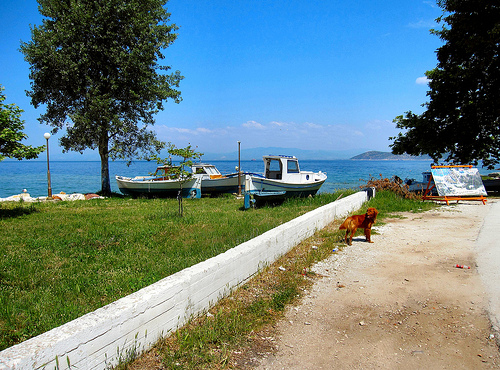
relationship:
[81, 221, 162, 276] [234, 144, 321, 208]
grass on boat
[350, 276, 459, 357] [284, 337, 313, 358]
floor covered in sand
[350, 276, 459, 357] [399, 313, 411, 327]
floor covered in dirt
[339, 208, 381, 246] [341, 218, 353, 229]
body with tail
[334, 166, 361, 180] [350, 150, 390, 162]
water across mountain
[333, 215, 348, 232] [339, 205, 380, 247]
tail on dog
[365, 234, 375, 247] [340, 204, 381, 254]
feet on dog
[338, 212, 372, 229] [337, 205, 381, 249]
body on dog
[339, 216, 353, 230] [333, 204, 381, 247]
tail on dog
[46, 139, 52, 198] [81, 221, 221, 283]
light pole on grass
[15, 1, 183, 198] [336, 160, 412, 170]
tree near ocean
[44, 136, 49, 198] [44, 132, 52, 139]
light pole with globe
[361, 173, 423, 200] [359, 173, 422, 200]
branch with branch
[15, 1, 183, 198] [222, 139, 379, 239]
tree beside boat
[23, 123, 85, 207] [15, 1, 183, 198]
street light behind tree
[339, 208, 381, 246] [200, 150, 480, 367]
body beside road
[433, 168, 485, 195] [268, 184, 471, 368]
sign in road